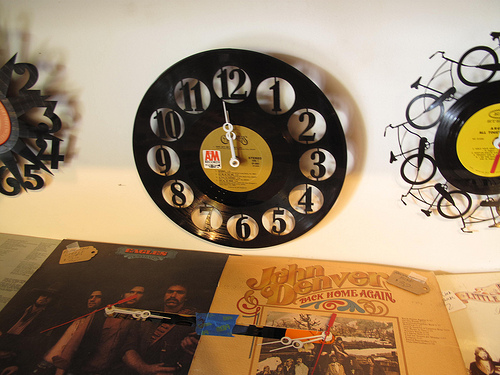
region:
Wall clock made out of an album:
[125, 43, 353, 248]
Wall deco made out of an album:
[381, 31, 498, 241]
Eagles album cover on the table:
[0, 238, 229, 374]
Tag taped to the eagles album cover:
[55, 240, 99, 267]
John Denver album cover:
[184, 251, 471, 373]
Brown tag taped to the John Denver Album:
[384, 267, 434, 298]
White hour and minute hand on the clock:
[213, 97, 243, 172]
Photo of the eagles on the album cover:
[3, 277, 202, 374]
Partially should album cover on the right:
[432, 270, 497, 373]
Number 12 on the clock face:
[210, 59, 255, 109]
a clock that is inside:
[111, 31, 499, 354]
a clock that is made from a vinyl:
[98, 21, 437, 354]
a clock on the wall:
[118, 33, 397, 290]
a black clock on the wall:
[57, 18, 497, 357]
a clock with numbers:
[161, 48, 461, 330]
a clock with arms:
[112, 27, 427, 275]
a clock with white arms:
[100, 51, 335, 257]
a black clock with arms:
[104, 51, 316, 242]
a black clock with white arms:
[123, 54, 350, 236]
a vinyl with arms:
[112, 14, 462, 284]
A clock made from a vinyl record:
[126, 32, 356, 266]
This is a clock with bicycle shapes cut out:
[383, 12, 497, 229]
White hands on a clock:
[211, 102, 243, 177]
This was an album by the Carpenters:
[186, 118, 272, 193]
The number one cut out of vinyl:
[257, 65, 296, 119]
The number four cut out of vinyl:
[31, 135, 68, 172]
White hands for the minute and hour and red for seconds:
[261, 309, 352, 366]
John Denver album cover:
[246, 259, 408, 314]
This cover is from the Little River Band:
[430, 276, 497, 358]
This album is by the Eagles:
[78, 237, 169, 342]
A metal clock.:
[142, 51, 347, 239]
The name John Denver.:
[241, 253, 388, 320]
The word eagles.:
[119, 244, 177, 265]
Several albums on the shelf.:
[0, 231, 480, 371]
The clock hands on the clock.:
[221, 103, 242, 179]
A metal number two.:
[12, 54, 41, 99]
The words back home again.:
[295, 288, 401, 319]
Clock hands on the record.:
[267, 317, 357, 356]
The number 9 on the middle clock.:
[154, 148, 176, 176]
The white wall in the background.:
[80, 10, 380, 41]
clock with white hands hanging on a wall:
[109, 40, 353, 258]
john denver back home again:
[244, 257, 444, 369]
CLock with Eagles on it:
[53, 223, 187, 369]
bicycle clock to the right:
[384, 44, 494, 257]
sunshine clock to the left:
[7, 40, 63, 230]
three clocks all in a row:
[5, 36, 485, 245]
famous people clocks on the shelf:
[75, 221, 490, 353]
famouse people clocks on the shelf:
[38, 230, 452, 354]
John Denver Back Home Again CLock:
[228, 248, 388, 317]